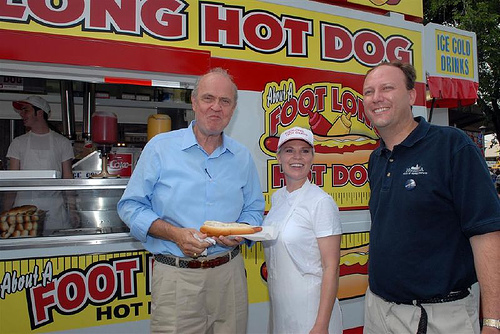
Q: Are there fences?
A: No, there are no fences.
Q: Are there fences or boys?
A: No, there are no fences or boys.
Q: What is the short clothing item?
A: The clothing item is a shirt.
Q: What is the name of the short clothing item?
A: The clothing item is a shirt.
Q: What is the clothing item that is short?
A: The clothing item is a shirt.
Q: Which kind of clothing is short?
A: The clothing is a shirt.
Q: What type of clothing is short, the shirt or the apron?
A: The shirt is short.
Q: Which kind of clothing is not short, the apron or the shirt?
A: The apron is not short.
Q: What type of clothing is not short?
A: The clothing is an apron.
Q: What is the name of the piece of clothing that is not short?
A: The clothing item is an apron.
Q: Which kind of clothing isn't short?
A: The clothing is an apron.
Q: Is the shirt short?
A: Yes, the shirt is short.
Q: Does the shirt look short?
A: Yes, the shirt is short.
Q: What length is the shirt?
A: The shirt is short.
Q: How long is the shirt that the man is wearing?
A: The shirt is short.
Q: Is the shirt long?
A: No, the shirt is short.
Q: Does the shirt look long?
A: No, the shirt is short.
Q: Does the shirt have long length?
A: No, the shirt is short.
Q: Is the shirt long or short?
A: The shirt is short.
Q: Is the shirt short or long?
A: The shirt is short.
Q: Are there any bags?
A: No, there are no bags.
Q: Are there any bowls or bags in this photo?
A: No, there are no bags or bowls.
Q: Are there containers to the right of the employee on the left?
A: Yes, there is a container to the right of the employee.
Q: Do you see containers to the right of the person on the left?
A: Yes, there is a container to the right of the employee.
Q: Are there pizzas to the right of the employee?
A: No, there is a container to the right of the employee.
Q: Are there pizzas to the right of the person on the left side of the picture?
A: No, there is a container to the right of the employee.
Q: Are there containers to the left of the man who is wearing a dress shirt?
A: Yes, there is a container to the left of the man.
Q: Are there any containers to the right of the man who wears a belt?
A: No, the container is to the left of the man.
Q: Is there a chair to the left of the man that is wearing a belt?
A: No, there is a container to the left of the man.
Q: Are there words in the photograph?
A: Yes, there are words.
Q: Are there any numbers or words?
A: Yes, there are words.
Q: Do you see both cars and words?
A: No, there are words but no cars.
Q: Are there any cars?
A: No, there are no cars.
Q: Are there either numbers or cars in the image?
A: No, there are no cars or numbers.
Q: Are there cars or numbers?
A: No, there are no cars or numbers.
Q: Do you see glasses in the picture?
A: No, there are no glasses.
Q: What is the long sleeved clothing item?
A: The clothing item is a dress shirt.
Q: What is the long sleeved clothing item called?
A: The clothing item is a dress shirt.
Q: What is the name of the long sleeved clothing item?
A: The clothing item is a dress shirt.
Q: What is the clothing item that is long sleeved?
A: The clothing item is a dress shirt.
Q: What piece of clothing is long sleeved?
A: The clothing item is a dress shirt.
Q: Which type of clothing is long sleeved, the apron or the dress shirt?
A: The dress shirt is long sleeved.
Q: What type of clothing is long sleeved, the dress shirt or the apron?
A: The dress shirt is long sleeved.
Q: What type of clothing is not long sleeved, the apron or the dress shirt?
A: The apron is not long sleeved.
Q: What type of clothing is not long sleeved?
A: The clothing is an apron.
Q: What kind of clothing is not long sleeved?
A: The clothing is an apron.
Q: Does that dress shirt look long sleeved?
A: Yes, the dress shirt is long sleeved.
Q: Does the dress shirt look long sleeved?
A: Yes, the dress shirt is long sleeved.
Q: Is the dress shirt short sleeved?
A: No, the dress shirt is long sleeved.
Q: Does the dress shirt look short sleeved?
A: No, the dress shirt is long sleeved.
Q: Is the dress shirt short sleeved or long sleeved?
A: The dress shirt is long sleeved.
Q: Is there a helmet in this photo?
A: No, there are no helmets.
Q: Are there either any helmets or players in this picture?
A: No, there are no helmets or players.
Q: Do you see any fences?
A: No, there are no fences.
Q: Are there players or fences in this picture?
A: No, there are no fences or players.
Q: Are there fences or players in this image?
A: No, there are no fences or players.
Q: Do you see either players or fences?
A: No, there are no fences or players.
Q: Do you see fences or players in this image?
A: No, there are no fences or players.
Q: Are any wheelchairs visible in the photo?
A: No, there are no wheelchairs.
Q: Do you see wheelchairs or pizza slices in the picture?
A: No, there are no wheelchairs or pizza slices.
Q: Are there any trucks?
A: Yes, there is a truck.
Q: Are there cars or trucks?
A: Yes, there is a truck.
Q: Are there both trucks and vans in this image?
A: No, there is a truck but no vans.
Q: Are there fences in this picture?
A: No, there are no fences.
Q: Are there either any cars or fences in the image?
A: No, there are no fences or cars.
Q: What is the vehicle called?
A: The vehicle is a truck.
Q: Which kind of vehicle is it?
A: The vehicle is a truck.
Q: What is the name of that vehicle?
A: This is a truck.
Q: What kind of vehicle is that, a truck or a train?
A: This is a truck.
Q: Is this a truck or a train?
A: This is a truck.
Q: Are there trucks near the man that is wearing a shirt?
A: Yes, there is a truck near the man.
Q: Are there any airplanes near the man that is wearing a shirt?
A: No, there is a truck near the man.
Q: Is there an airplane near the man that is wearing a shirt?
A: No, there is a truck near the man.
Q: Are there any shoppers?
A: No, there are no shoppers.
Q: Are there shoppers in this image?
A: No, there are no shoppers.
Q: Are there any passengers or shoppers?
A: No, there are no shoppers or passengers.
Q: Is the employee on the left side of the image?
A: Yes, the employee is on the left of the image.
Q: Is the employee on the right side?
A: No, the employee is on the left of the image.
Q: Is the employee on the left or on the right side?
A: The employee is on the left of the image.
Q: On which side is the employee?
A: The employee is on the left of the image.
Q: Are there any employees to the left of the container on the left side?
A: Yes, there is an employee to the left of the container.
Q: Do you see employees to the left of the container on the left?
A: Yes, there is an employee to the left of the container.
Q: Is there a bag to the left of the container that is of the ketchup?
A: No, there is an employee to the left of the container.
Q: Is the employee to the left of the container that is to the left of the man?
A: Yes, the employee is to the left of the container.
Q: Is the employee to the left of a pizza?
A: No, the employee is to the left of the container.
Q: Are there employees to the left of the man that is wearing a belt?
A: Yes, there is an employee to the left of the man.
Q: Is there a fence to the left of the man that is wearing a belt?
A: No, there is an employee to the left of the man.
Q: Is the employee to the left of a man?
A: Yes, the employee is to the left of a man.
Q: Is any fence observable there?
A: No, there are no fences.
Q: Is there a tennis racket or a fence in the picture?
A: No, there are no fences or rackets.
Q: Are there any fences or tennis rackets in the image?
A: No, there are no fences or tennis rackets.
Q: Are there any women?
A: Yes, there is a woman.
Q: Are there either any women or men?
A: Yes, there is a woman.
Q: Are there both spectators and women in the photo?
A: No, there is a woman but no spectators.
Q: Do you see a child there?
A: No, there are no children.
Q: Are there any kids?
A: No, there are no kids.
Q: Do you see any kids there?
A: No, there are no kids.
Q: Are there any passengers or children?
A: No, there are no children or passengers.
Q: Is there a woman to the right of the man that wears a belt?
A: Yes, there is a woman to the right of the man.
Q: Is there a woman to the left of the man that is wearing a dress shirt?
A: No, the woman is to the right of the man.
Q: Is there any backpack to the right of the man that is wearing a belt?
A: No, there is a woman to the right of the man.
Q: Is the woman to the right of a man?
A: Yes, the woman is to the right of a man.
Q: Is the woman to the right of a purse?
A: No, the woman is to the right of a man.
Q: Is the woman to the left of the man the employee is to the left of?
A: No, the woman is to the right of the man.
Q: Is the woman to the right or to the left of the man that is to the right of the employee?
A: The woman is to the right of the man.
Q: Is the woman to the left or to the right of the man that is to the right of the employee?
A: The woman is to the right of the man.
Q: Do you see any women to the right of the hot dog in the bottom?
A: Yes, there is a woman to the right of the hot dog.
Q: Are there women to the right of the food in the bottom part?
A: Yes, there is a woman to the right of the hot dog.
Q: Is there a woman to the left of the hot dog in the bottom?
A: No, the woman is to the right of the hot dog.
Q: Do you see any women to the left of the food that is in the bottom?
A: No, the woman is to the right of the hot dog.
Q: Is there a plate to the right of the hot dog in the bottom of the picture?
A: No, there is a woman to the right of the hot dog.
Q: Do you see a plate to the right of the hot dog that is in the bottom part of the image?
A: No, there is a woman to the right of the hot dog.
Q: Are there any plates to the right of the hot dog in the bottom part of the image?
A: No, there is a woman to the right of the hot dog.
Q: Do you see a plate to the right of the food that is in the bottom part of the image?
A: No, there is a woman to the right of the hot dog.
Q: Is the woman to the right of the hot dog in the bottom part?
A: Yes, the woman is to the right of the hot dog.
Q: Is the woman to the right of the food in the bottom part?
A: Yes, the woman is to the right of the hot dog.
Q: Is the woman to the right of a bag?
A: No, the woman is to the right of the hot dog.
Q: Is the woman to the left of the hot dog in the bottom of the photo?
A: No, the woman is to the right of the hot dog.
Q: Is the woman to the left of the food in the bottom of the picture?
A: No, the woman is to the right of the hot dog.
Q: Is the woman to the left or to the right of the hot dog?
A: The woman is to the right of the hot dog.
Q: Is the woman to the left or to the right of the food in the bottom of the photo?
A: The woman is to the right of the hot dog.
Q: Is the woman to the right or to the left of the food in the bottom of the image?
A: The woman is to the right of the hot dog.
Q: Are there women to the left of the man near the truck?
A: Yes, there is a woman to the left of the man.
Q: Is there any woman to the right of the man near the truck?
A: No, the woman is to the left of the man.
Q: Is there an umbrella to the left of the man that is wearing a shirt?
A: No, there is a woman to the left of the man.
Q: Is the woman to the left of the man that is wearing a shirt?
A: Yes, the woman is to the left of the man.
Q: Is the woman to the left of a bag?
A: No, the woman is to the left of the man.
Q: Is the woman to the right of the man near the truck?
A: No, the woman is to the left of the man.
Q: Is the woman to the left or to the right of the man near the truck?
A: The woman is to the left of the man.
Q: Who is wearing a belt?
A: The woman is wearing a belt.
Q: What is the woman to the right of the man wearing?
A: The woman is wearing a belt.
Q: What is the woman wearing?
A: The woman is wearing a belt.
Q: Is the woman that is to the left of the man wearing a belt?
A: Yes, the woman is wearing a belt.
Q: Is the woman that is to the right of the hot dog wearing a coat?
A: No, the woman is wearing a belt.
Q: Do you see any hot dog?
A: Yes, there is a hot dog.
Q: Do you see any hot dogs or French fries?
A: Yes, there is a hot dog.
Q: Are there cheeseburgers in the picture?
A: No, there are no cheeseburgers.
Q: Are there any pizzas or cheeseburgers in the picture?
A: No, there are no cheeseburgers or pizzas.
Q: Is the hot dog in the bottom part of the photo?
A: Yes, the hot dog is in the bottom of the image.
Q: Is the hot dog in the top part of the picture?
A: No, the hot dog is in the bottom of the image.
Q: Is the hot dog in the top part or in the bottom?
A: The hot dog is in the bottom of the image.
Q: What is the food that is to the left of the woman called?
A: The food is a hot dog.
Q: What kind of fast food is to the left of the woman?
A: The food is a hot dog.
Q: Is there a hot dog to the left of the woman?
A: Yes, there is a hot dog to the left of the woman.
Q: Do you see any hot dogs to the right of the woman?
A: No, the hot dog is to the left of the woman.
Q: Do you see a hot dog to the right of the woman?
A: No, the hot dog is to the left of the woman.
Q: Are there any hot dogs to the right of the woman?
A: No, the hot dog is to the left of the woman.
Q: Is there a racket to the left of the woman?
A: No, there is a hot dog to the left of the woman.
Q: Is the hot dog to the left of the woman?
A: Yes, the hot dog is to the left of the woman.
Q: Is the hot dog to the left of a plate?
A: No, the hot dog is to the left of the woman.